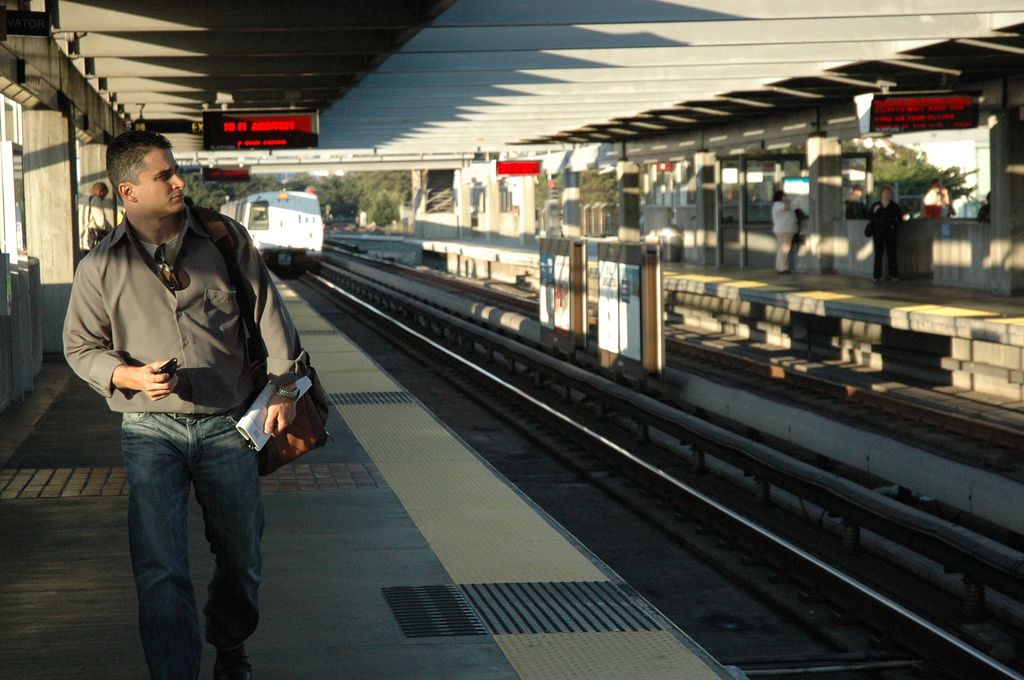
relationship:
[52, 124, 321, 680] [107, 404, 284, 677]
man wearing blue jeans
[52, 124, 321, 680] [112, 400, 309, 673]
man wearing jeans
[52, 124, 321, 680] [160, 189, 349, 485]
man carrying a bag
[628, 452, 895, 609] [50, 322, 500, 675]
rod on ground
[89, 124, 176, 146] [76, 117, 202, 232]
hair on head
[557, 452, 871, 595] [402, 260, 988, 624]
rod on train tracks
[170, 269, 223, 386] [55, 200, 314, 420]
wrinkle on gray shirt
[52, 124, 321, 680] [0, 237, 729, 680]
man on platform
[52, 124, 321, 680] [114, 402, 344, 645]
man wearing jeans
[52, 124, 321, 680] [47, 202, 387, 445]
man wearing shirt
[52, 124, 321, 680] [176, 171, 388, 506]
man wearing bag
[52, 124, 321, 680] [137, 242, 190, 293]
man wearing sunglasses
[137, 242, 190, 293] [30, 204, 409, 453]
sunglasses in shirt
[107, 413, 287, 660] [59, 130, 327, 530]
blue jeans on man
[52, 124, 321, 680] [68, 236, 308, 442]
man wearing gray shirt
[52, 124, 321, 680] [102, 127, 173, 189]
man has hair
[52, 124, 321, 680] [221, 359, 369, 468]
man has bag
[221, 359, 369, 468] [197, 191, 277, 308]
bag on shoulder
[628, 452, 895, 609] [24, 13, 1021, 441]
rod in train station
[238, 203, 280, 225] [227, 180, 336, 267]
window on train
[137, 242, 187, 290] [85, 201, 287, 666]
sunglasses on man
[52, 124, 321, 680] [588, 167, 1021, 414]
man standing on platform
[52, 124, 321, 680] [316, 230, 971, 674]
man walking by train tracks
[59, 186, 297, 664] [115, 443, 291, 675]
man wearing pants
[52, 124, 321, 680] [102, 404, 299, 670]
man wearing jeans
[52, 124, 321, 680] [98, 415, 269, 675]
man wearing jeans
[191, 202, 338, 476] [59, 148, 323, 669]
bag on man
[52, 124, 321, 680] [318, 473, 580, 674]
man on platform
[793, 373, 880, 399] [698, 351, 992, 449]
shadow on tracks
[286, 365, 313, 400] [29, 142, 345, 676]
watch on man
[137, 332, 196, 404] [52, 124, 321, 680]
cellphone on man